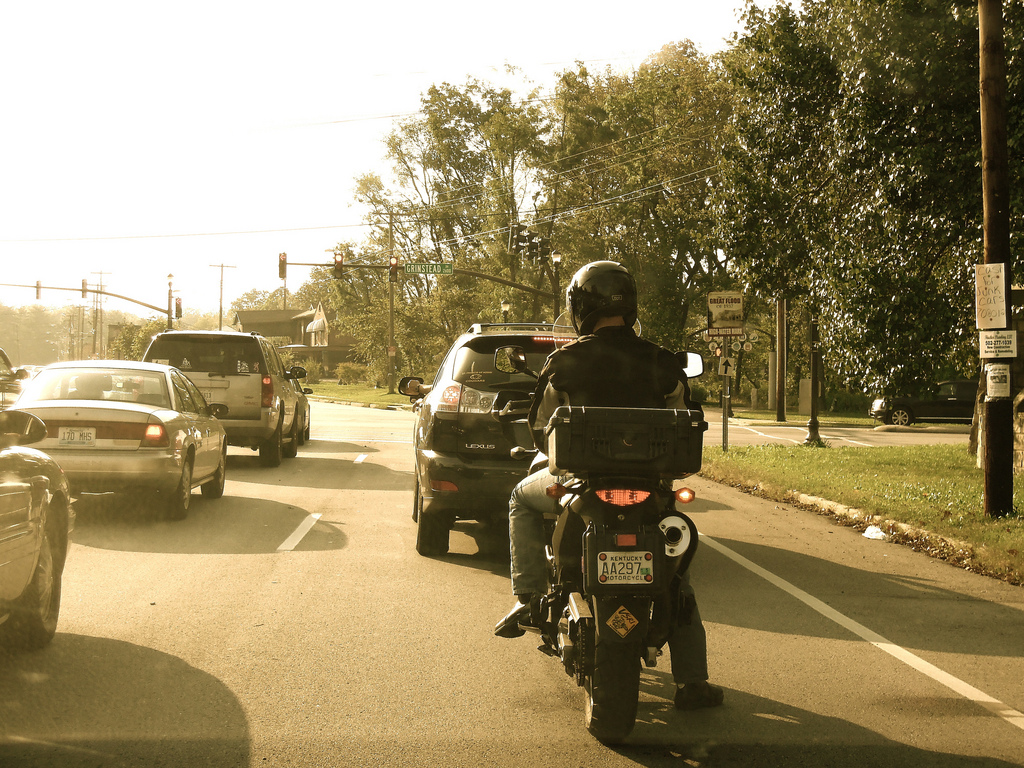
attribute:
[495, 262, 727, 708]
rider — wearing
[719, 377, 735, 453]
sign — white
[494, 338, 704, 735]
motorcycle — black 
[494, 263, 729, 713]
person — wearing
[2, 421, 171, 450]
brake light — glowing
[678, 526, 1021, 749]
line — straight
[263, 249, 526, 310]
pole — horizontal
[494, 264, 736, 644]
rider — sitting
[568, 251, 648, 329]
head — rider's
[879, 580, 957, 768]
line — white and solid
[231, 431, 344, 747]
dash marks — white 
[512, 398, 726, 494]
case — black